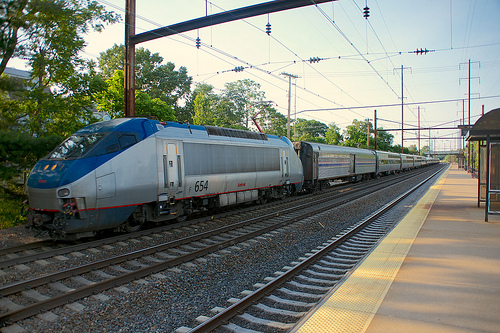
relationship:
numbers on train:
[193, 177, 209, 194] [20, 110, 442, 241]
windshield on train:
[48, 126, 137, 159] [20, 110, 442, 241]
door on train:
[152, 132, 188, 192] [20, 110, 442, 241]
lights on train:
[38, 158, 61, 173] [20, 110, 442, 241]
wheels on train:
[122, 199, 197, 231] [20, 110, 442, 241]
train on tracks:
[20, 110, 442, 241] [0, 166, 450, 331]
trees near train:
[0, 3, 429, 150] [20, 110, 442, 241]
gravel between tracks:
[157, 171, 433, 287] [0, 166, 450, 331]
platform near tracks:
[294, 155, 500, 332] [0, 166, 450, 331]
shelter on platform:
[466, 108, 499, 222] [294, 155, 500, 332]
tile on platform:
[294, 159, 452, 331] [294, 155, 500, 332]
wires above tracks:
[128, 0, 499, 148] [0, 166, 450, 331]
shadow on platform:
[333, 190, 497, 332] [294, 155, 500, 332]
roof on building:
[0, 66, 41, 80] [0, 65, 50, 151]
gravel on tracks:
[157, 171, 433, 287] [0, 166, 450, 331]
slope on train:
[20, 106, 167, 193] [20, 110, 442, 241]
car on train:
[27, 120, 306, 242] [20, 110, 442, 241]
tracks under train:
[0, 166, 450, 331] [20, 110, 442, 241]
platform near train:
[294, 155, 500, 332] [20, 110, 442, 241]